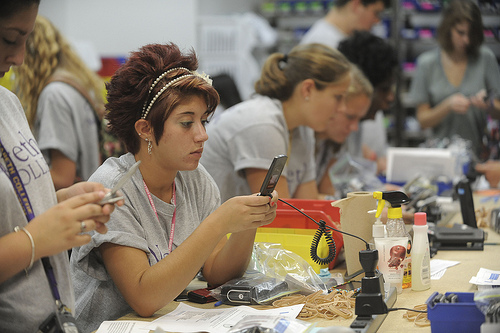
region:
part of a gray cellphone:
[260, 153, 288, 197]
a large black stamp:
[350, 246, 392, 312]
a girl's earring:
[144, 138, 154, 153]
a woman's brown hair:
[252, 38, 352, 105]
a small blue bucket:
[425, 284, 486, 331]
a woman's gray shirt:
[410, 47, 499, 139]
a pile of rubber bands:
[281, 283, 356, 320]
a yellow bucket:
[224, 225, 330, 272]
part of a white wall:
[43, 0, 191, 55]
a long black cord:
[267, 192, 365, 245]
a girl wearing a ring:
[62, 202, 98, 255]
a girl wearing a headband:
[149, 53, 196, 112]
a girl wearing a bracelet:
[14, 193, 44, 282]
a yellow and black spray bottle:
[372, 176, 417, 239]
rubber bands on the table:
[283, 277, 361, 325]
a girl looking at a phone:
[256, 138, 288, 233]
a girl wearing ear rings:
[136, 115, 167, 165]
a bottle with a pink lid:
[404, 198, 443, 296]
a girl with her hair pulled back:
[242, 28, 358, 118]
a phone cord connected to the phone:
[284, 174, 387, 285]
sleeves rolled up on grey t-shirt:
[75, 209, 152, 284]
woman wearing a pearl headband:
[117, 40, 220, 179]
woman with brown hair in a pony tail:
[250, 29, 359, 142]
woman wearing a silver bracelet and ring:
[14, 170, 111, 283]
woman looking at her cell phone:
[136, 44, 288, 275]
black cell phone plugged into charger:
[235, 135, 391, 320]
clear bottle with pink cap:
[400, 204, 447, 292]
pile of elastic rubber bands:
[277, 283, 356, 322]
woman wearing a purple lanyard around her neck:
[2, 68, 79, 321]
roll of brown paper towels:
[325, 181, 377, 274]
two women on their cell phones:
[1, 2, 296, 313]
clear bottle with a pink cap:
[404, 206, 439, 289]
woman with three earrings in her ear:
[130, 114, 162, 167]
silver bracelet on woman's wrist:
[17, 204, 39, 279]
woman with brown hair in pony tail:
[252, 38, 353, 136]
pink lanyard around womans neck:
[145, 164, 196, 254]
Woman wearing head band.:
[95, 32, 215, 176]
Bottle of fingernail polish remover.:
[409, 203, 434, 294]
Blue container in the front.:
[426, 284, 486, 331]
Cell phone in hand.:
[250, 152, 290, 218]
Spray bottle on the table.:
[370, 180, 413, 290]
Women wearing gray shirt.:
[401, 0, 497, 157]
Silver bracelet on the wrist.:
[10, 220, 51, 277]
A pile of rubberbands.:
[265, 285, 360, 325]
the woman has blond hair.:
[13, 13, 106, 177]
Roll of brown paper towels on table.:
[334, 186, 379, 276]